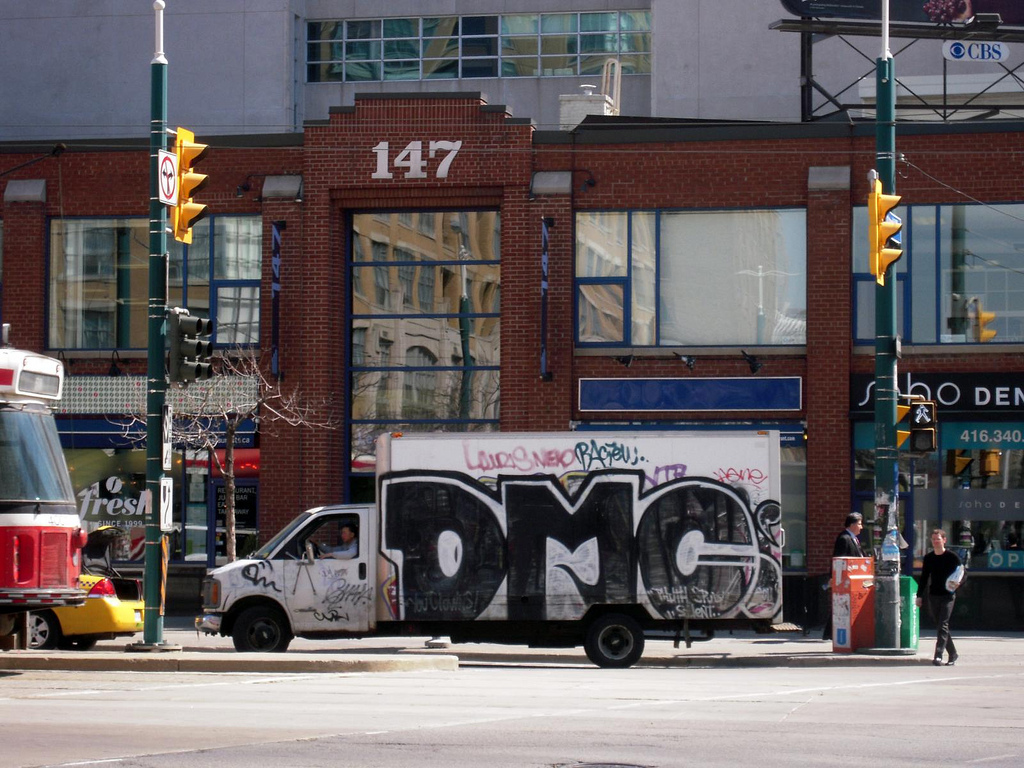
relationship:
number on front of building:
[363, 124, 474, 192] [6, 5, 992, 613]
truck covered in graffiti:
[188, 421, 792, 659] [378, 458, 780, 638]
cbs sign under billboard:
[938, 39, 991, 63] [780, 1, 981, 120]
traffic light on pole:
[169, 124, 212, 247] [140, 3, 175, 654]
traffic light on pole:
[169, 121, 217, 255] [136, 1, 173, 658]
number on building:
[366, 138, 464, 183] [6, 5, 992, 613]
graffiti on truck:
[378, 458, 780, 638] [191, 427, 787, 671]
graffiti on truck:
[378, 438, 780, 638] [188, 421, 792, 659]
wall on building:
[347, 210, 503, 472] [245, 77, 575, 543]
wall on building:
[361, 310, 481, 427] [251, 88, 539, 536]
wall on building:
[347, 210, 503, 472] [269, 85, 544, 513]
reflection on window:
[341, 205, 512, 454] [330, 198, 519, 488]